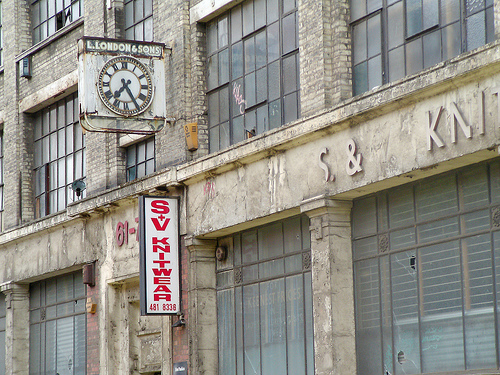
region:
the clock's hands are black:
[95, 55, 155, 126]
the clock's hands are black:
[103, 59, 143, 112]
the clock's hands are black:
[108, 68, 138, 99]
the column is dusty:
[300, 205, 364, 373]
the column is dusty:
[0, 279, 48, 372]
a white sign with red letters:
[126, 165, 197, 353]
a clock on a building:
[70, 36, 170, 136]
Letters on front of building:
[284, 74, 499, 184]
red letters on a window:
[220, 76, 251, 118]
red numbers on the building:
[101, 218, 154, 258]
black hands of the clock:
[114, 78, 142, 110]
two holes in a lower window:
[385, 242, 428, 374]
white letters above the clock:
[83, 33, 173, 58]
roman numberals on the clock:
[95, 62, 165, 114]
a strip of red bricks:
[79, 261, 106, 373]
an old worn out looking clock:
[74, 33, 171, 135]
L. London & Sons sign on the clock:
[86, 40, 163, 56]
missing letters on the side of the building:
[293, 91, 498, 191]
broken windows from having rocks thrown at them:
[378, 245, 431, 370]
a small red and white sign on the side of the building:
[143, 193, 183, 319]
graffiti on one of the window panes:
[231, 80, 250, 112]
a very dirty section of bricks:
[152, 4, 207, 164]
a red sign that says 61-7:
[115, 214, 145, 251]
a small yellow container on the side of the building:
[180, 120, 200, 153]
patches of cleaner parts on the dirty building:
[225, 151, 299, 216]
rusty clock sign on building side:
[69, 31, 176, 141]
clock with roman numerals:
[97, 53, 158, 123]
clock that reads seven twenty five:
[91, 53, 155, 123]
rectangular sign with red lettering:
[136, 191, 184, 316]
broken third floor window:
[45, 5, 76, 30]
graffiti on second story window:
[226, 79, 250, 118]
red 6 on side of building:
[112, 220, 126, 250]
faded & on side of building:
[343, 138, 361, 180]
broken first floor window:
[401, 252, 424, 271]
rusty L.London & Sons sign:
[80, 34, 168, 61]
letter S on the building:
[310, 138, 337, 198]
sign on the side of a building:
[138, 180, 178, 317]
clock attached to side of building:
[71, 30, 180, 136]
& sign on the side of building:
[346, 135, 369, 190]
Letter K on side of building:
[422, 93, 452, 163]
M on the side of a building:
[444, 94, 491, 153]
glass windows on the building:
[352, 198, 496, 356]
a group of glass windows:
[206, 29, 300, 128]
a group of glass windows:
[33, 112, 86, 202]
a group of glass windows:
[35, 290, 88, 370]